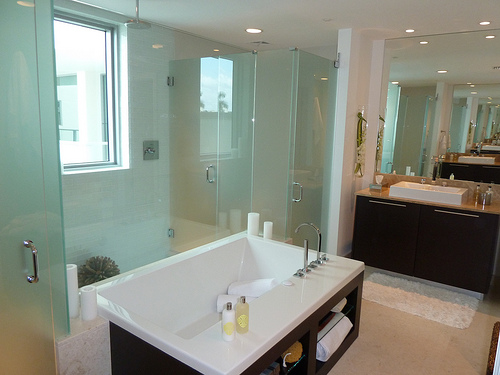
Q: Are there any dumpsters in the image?
A: No, there are no dumpsters.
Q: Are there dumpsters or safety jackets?
A: No, there are no dumpsters or safety jackets.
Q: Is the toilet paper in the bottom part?
A: Yes, the toilet paper is in the bottom of the image.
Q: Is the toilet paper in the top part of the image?
A: No, the toilet paper is in the bottom of the image.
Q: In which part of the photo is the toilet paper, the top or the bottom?
A: The toilet paper is in the bottom of the image.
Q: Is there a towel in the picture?
A: Yes, there is a towel.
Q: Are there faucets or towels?
A: Yes, there is a towel.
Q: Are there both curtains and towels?
A: No, there is a towel but no curtains.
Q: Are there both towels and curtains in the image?
A: No, there is a towel but no curtains.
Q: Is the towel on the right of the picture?
A: No, the towel is on the left of the image.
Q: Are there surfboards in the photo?
A: No, there are no surfboards.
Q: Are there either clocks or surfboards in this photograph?
A: No, there are no surfboards or clocks.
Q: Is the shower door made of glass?
A: Yes, the shower door is made of glass.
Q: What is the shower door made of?
A: The shower door is made of glass.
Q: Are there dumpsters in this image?
A: No, there are no dumpsters.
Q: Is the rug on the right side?
A: Yes, the rug is on the right of the image.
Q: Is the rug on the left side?
A: No, the rug is on the right of the image.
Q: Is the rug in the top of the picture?
A: No, the rug is in the bottom of the image.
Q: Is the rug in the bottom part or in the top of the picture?
A: The rug is in the bottom of the image.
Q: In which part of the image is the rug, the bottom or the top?
A: The rug is in the bottom of the image.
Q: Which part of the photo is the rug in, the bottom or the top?
A: The rug is in the bottom of the image.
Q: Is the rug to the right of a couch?
A: No, the rug is to the right of a bottle.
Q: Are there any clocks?
A: No, there are no clocks.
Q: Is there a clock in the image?
A: No, there are no clocks.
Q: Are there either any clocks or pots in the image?
A: No, there are no clocks or pots.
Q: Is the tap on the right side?
A: Yes, the tap is on the right of the image.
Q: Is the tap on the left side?
A: No, the tap is on the right of the image.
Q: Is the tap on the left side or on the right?
A: The tap is on the right of the image.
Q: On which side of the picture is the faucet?
A: The faucet is on the right of the image.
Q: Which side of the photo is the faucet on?
A: The faucet is on the right of the image.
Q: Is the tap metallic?
A: Yes, the tap is metallic.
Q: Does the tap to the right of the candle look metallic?
A: Yes, the faucet is metallic.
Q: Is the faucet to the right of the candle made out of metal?
A: Yes, the faucet is made of metal.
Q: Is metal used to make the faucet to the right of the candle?
A: Yes, the faucet is made of metal.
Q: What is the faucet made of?
A: The faucet is made of metal.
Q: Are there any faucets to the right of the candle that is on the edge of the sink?
A: Yes, there is a faucet to the right of the candle.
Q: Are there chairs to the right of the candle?
A: No, there is a faucet to the right of the candle.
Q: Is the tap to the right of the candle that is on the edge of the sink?
A: Yes, the tap is to the right of the candle.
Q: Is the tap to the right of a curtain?
A: No, the tap is to the right of the candle.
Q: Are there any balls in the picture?
A: Yes, there is a ball.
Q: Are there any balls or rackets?
A: Yes, there is a ball.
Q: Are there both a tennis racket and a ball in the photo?
A: No, there is a ball but no rackets.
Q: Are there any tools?
A: No, there are no tools.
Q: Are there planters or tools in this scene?
A: No, there are no tools or planters.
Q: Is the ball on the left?
A: Yes, the ball is on the left of the image.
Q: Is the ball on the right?
A: No, the ball is on the left of the image.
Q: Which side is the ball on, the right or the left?
A: The ball is on the left of the image.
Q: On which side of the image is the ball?
A: The ball is on the left of the image.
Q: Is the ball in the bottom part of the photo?
A: Yes, the ball is in the bottom of the image.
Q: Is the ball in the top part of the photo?
A: No, the ball is in the bottom of the image.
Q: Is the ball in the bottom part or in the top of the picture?
A: The ball is in the bottom of the image.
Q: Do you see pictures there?
A: No, there are no pictures.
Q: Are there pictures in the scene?
A: No, there are no pictures.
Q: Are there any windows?
A: Yes, there is a window.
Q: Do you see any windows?
A: Yes, there is a window.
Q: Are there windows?
A: Yes, there is a window.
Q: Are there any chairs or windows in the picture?
A: Yes, there is a window.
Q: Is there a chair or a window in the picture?
A: Yes, there is a window.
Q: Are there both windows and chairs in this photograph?
A: No, there is a window but no chairs.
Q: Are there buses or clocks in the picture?
A: No, there are no clocks or buses.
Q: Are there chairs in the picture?
A: No, there are no chairs.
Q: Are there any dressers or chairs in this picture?
A: No, there are no chairs or dressers.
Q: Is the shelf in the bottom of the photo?
A: Yes, the shelf is in the bottom of the image.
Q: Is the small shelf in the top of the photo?
A: No, the shelf is in the bottom of the image.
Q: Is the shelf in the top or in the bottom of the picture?
A: The shelf is in the bottom of the image.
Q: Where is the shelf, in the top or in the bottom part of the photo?
A: The shelf is in the bottom of the image.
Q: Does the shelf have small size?
A: Yes, the shelf is small.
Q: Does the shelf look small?
A: Yes, the shelf is small.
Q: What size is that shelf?
A: The shelf is small.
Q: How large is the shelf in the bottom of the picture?
A: The shelf is small.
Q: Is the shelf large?
A: No, the shelf is small.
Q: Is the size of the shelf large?
A: No, the shelf is small.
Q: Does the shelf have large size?
A: No, the shelf is small.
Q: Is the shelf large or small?
A: The shelf is small.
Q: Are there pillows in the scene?
A: No, there are no pillows.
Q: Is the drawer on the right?
A: Yes, the drawer is on the right of the image.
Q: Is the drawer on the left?
A: No, the drawer is on the right of the image.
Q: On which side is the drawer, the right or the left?
A: The drawer is on the right of the image.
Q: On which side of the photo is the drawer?
A: The drawer is on the right of the image.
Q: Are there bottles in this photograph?
A: Yes, there is a bottle.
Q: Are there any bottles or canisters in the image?
A: Yes, there is a bottle.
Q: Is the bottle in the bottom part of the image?
A: Yes, the bottle is in the bottom of the image.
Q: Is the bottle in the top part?
A: No, the bottle is in the bottom of the image.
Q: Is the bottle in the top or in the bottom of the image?
A: The bottle is in the bottom of the image.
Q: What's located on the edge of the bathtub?
A: The bottle is on the edge of the bathtub.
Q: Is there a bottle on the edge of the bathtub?
A: Yes, there is a bottle on the edge of the bathtub.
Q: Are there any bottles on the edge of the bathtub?
A: Yes, there is a bottle on the edge of the bathtub.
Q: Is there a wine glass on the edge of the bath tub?
A: No, there is a bottle on the edge of the bath tub.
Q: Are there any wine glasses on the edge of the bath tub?
A: No, there is a bottle on the edge of the bath tub.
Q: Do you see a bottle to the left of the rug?
A: Yes, there is a bottle to the left of the rug.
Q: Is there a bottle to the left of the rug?
A: Yes, there is a bottle to the left of the rug.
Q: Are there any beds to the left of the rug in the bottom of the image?
A: No, there is a bottle to the left of the rug.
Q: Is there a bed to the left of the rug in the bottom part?
A: No, there is a bottle to the left of the rug.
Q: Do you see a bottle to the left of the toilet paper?
A: Yes, there is a bottle to the left of the toilet paper.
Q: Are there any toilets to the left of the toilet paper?
A: No, there is a bottle to the left of the toilet paper.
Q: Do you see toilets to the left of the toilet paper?
A: No, there is a bottle to the left of the toilet paper.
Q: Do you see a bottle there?
A: Yes, there is a bottle.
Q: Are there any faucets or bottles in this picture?
A: Yes, there is a bottle.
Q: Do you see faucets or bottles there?
A: Yes, there is a bottle.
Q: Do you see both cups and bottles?
A: No, there is a bottle but no cups.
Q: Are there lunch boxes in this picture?
A: No, there are no lunch boxes.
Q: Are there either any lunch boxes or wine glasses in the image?
A: No, there are no lunch boxes or wine glasses.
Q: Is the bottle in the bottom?
A: Yes, the bottle is in the bottom of the image.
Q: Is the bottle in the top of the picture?
A: No, the bottle is in the bottom of the image.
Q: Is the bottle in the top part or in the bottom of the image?
A: The bottle is in the bottom of the image.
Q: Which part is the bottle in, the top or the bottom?
A: The bottle is in the bottom of the image.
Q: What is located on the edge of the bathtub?
A: The bottle is on the edge of the bathtub.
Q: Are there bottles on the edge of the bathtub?
A: Yes, there is a bottle on the edge of the bathtub.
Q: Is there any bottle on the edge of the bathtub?
A: Yes, there is a bottle on the edge of the bathtub.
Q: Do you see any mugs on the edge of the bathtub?
A: No, there is a bottle on the edge of the bathtub.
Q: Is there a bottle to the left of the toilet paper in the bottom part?
A: Yes, there is a bottle to the left of the toilet paper.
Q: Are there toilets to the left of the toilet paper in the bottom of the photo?
A: No, there is a bottle to the left of the toilet paper.